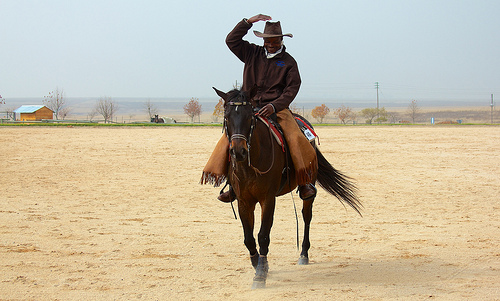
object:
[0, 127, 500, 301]
field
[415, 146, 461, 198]
sand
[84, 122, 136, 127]
grass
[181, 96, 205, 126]
trees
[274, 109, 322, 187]
chaps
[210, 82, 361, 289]
horse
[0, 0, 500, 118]
sky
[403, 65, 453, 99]
dust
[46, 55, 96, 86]
air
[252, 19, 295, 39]
cowboy hat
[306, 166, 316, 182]
fringe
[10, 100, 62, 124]
building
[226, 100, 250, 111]
reins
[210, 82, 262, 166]
horse head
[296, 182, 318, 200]
foot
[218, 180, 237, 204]
stirrup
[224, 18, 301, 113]
jacket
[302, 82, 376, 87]
powerline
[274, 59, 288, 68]
writing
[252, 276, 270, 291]
hoof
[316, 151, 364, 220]
tail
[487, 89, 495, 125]
telephone pole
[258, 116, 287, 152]
saddle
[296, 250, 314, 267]
hoofs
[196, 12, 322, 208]
cowboy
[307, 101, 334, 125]
trees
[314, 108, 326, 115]
orange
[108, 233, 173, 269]
terrain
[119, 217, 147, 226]
footprints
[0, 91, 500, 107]
horizon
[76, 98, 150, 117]
distance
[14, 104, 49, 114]
roof